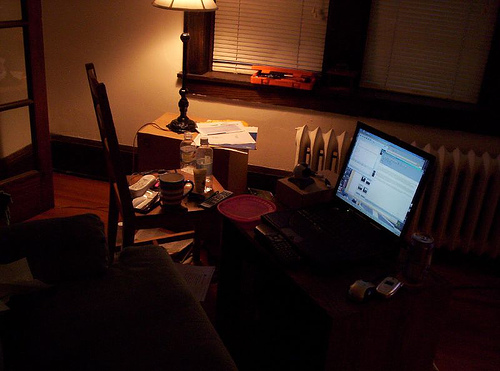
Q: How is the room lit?
A: Lamp.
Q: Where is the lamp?
A: On the table.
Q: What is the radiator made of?
A: Cast iron.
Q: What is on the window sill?
A: Orange tool box.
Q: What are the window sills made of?
A: Wood.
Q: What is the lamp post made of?
A: Iron.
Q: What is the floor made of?
A: Wood.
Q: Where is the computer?
A: On the desk.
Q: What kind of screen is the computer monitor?
A: Flat screen.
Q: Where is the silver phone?
A: Next to computer.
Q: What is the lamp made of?
A: Metal.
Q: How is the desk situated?
A: Cornered.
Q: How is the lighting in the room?
A: Dim.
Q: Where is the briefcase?
A: Window sill.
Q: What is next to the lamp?
A: Papers.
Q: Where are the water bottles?
A: On the chair.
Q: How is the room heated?
A: Radiator.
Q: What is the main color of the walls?
A: White.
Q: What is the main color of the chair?
A: Brown.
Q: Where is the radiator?
A: Behind the desk.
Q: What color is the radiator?
A: White.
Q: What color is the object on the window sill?
A: Orange.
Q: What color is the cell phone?
A: Silver.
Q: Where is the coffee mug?
A: On the chair.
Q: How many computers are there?
A: One.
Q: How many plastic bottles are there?
A: Two.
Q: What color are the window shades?
A: White.